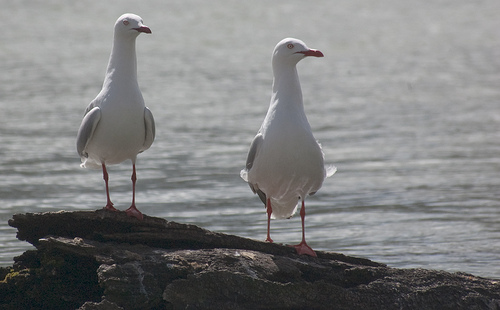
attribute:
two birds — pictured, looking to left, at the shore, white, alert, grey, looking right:
[77, 11, 339, 262]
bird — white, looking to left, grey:
[240, 31, 330, 261]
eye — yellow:
[284, 40, 297, 53]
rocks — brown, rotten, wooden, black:
[3, 209, 497, 308]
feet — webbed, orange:
[263, 235, 319, 260]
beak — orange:
[300, 45, 326, 60]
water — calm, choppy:
[1, 1, 499, 276]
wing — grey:
[72, 110, 99, 156]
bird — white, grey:
[74, 14, 158, 225]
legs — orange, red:
[262, 195, 307, 244]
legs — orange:
[100, 163, 139, 208]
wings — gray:
[75, 109, 157, 158]